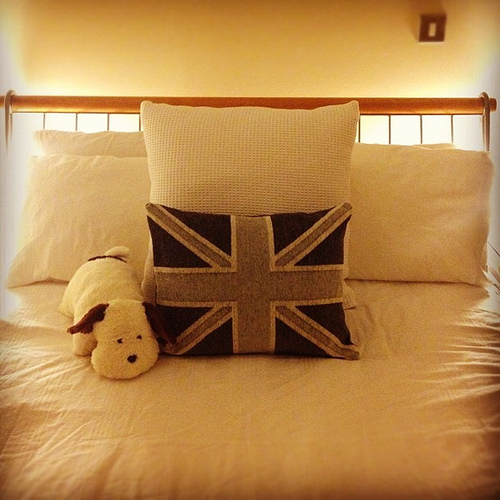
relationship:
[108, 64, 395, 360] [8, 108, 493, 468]
pillow on bed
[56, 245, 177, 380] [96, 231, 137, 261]
animal has tail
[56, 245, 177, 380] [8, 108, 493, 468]
animal on bed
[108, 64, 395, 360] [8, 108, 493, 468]
pillow of bed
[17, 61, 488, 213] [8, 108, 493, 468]
headboard of bed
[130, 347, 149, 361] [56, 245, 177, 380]
nose of animal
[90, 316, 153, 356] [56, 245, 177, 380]
eye of animal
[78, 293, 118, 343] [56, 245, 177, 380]
ear of animal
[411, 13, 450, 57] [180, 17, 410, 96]
switch on wall